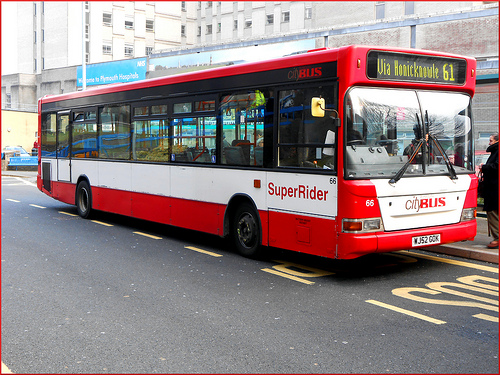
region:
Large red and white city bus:
[28, 56, 474, 268]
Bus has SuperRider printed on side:
[241, 164, 334, 209]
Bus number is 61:
[428, 55, 462, 88]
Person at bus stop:
[478, 128, 498, 248]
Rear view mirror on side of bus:
[294, 78, 347, 172]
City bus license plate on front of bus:
[398, 226, 453, 258]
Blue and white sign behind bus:
[66, 53, 153, 98]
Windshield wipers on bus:
[378, 107, 464, 195]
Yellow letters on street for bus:
[392, 266, 491, 342]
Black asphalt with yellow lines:
[160, 264, 392, 356]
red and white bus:
[21, 36, 496, 306]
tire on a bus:
[219, 172, 288, 257]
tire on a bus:
[70, 161, 101, 216]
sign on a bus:
[345, 33, 482, 95]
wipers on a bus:
[395, 111, 461, 192]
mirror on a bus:
[310, 88, 340, 140]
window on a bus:
[206, 87, 259, 160]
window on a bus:
[166, 85, 221, 170]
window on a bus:
[125, 86, 170, 162]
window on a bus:
[71, 99, 108, 172]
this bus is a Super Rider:
[25, 31, 478, 301]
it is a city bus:
[399, 186, 465, 228]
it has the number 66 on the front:
[360, 188, 386, 218]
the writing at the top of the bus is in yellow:
[368, 52, 483, 89]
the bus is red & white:
[11, 55, 490, 288]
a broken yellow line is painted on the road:
[35, 188, 455, 372]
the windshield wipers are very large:
[393, 104, 467, 208]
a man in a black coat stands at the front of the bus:
[478, 124, 498, 250]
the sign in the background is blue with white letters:
[57, 34, 157, 87]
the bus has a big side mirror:
[298, 81, 350, 143]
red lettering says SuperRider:
[267, 177, 340, 207]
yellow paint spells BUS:
[412, 259, 498, 367]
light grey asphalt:
[20, 246, 310, 373]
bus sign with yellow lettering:
[367, 47, 472, 96]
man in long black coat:
[477, 134, 498, 239]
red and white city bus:
[30, 31, 498, 253]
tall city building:
[13, 5, 220, 67]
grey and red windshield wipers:
[395, 127, 470, 184]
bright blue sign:
[76, 57, 157, 85]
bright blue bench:
[8, 147, 45, 171]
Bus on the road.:
[28, 39, 484, 285]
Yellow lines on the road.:
[223, 246, 468, 337]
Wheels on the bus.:
[188, 198, 298, 249]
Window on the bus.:
[306, 60, 489, 185]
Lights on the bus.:
[335, 147, 472, 247]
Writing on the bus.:
[213, 161, 384, 259]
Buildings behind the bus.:
[85, 8, 453, 173]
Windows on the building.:
[171, 10, 407, 85]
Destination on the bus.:
[240, 50, 490, 101]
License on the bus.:
[397, 220, 467, 263]